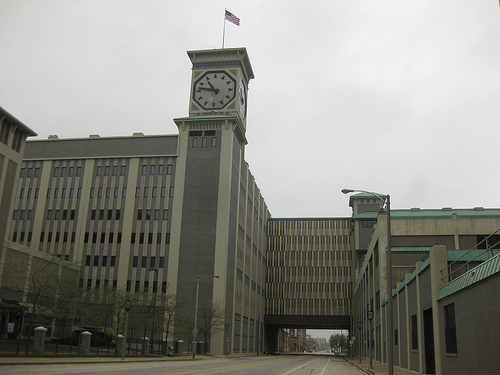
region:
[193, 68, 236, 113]
white face of the clock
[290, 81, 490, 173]
grey cloudy skies over the building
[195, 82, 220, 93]
black hands of the clock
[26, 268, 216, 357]
several trees in the courtyard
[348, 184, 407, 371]
a street light next to the building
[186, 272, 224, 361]
a street light next to the courtyard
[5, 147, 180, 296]
many windows on the building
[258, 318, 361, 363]
an underpass going through the building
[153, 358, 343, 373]
black asphalt of the road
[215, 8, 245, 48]
American flag on top of the building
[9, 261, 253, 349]
trees at the sidewalk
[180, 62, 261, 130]
a big octagon clock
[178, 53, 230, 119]
a big octagon clock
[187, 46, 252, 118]
clock on a tower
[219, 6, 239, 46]
flag on top of a clock tower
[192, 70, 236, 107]
clock face on the clock tower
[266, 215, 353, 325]
bridge walkway area of the building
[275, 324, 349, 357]
passageway under the building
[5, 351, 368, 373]
street goes under the building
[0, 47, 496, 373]
large gray building with a clock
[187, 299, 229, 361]
medium tree on the ground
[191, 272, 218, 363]
light post on the sidewalk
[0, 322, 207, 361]
fence along a sidewalk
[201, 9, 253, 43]
the US flag on the roof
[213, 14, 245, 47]
the US flag on the roof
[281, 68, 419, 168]
the sky is overcast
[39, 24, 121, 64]
the sky is overcast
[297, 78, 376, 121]
the sky is overcast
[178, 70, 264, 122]
clock's hands are black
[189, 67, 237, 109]
clock's hands are black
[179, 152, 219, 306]
the wall is tall and gray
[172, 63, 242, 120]
a clock on the building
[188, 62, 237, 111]
the numbers are triangles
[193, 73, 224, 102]
the hands on the clock are black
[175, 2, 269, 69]
an flag on top of the clock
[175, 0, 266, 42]
an american flag on top the building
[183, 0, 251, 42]
the flag is on a pole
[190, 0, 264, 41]
the flag is red, white, and blue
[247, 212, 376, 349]
a walkway between the buildings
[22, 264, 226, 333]
the trees are bare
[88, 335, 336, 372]
the street is empty